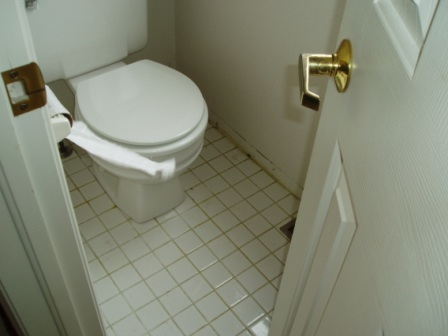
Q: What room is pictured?
A: It is a bathroom.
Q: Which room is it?
A: It is a bathroom.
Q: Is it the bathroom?
A: Yes, it is the bathroom.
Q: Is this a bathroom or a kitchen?
A: It is a bathroom.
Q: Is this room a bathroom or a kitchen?
A: It is a bathroom.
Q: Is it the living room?
A: No, it is the bathroom.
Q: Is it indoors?
A: Yes, it is indoors.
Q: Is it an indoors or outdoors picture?
A: It is indoors.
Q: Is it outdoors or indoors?
A: It is indoors.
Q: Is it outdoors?
A: No, it is indoors.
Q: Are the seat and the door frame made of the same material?
A: Yes, both the seat and the door frame are made of wood.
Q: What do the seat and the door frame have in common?
A: The material, both the seat and the door frame are wooden.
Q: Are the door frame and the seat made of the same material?
A: Yes, both the door frame and the seat are made of wood.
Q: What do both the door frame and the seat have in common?
A: The material, both the door frame and the seat are wooden.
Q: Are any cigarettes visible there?
A: No, there are no cigarettes.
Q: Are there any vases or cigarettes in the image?
A: No, there are no cigarettes or vases.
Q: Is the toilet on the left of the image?
A: Yes, the toilet is on the left of the image.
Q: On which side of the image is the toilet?
A: The toilet is on the left of the image.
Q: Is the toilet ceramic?
A: Yes, the toilet is ceramic.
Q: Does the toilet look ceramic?
A: Yes, the toilet is ceramic.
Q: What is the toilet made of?
A: The toilet is made of porcelain.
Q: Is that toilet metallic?
A: No, the toilet is ceramic.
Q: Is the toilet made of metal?
A: No, the toilet is made of porcelain.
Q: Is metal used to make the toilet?
A: No, the toilet is made of porcelain.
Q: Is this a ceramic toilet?
A: Yes, this is a ceramic toilet.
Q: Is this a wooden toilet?
A: No, this is a ceramic toilet.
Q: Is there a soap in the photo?
A: No, there are no soaps.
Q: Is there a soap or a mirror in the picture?
A: No, there are no soaps or mirrors.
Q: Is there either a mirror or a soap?
A: No, there are no soaps or mirrors.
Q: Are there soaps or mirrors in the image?
A: No, there are no soaps or mirrors.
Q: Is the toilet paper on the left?
A: Yes, the toilet paper is on the left of the image.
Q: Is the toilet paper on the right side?
A: No, the toilet paper is on the left of the image.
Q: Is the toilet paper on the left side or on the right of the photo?
A: The toilet paper is on the left of the image.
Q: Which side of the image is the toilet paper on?
A: The toilet paper is on the left of the image.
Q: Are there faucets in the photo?
A: No, there are no faucets.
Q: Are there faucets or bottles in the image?
A: No, there are no faucets or bottles.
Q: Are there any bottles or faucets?
A: No, there are no faucets or bottles.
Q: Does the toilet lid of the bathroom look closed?
A: Yes, the toilet lid is closed.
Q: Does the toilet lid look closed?
A: Yes, the toilet lid is closed.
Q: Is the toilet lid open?
A: No, the toilet lid is closed.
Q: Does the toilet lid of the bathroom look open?
A: No, the toilet lid is closed.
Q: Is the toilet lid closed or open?
A: The toilet lid is closed.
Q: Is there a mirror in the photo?
A: No, there are no mirrors.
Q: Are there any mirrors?
A: No, there are no mirrors.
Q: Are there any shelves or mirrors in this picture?
A: No, there are no mirrors or shelves.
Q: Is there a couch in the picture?
A: No, there are no couches.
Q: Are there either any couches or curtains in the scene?
A: No, there are no couches or curtains.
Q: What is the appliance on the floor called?
A: The appliance is a heater.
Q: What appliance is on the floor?
A: The appliance is a heater.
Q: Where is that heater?
A: The heater is on the floor.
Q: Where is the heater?
A: The heater is on the floor.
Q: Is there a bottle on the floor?
A: No, there is a heater on the floor.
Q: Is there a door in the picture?
A: Yes, there is a door.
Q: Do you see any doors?
A: Yes, there is a door.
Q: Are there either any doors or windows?
A: Yes, there is a door.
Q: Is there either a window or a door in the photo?
A: Yes, there is a door.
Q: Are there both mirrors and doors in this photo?
A: No, there is a door but no mirrors.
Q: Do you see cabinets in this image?
A: No, there are no cabinets.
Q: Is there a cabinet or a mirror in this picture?
A: No, there are no cabinets or mirrors.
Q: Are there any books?
A: No, there are no books.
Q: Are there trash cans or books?
A: No, there are no books or trash cans.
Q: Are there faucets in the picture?
A: No, there are no faucets.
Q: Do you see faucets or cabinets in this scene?
A: No, there are no faucets or cabinets.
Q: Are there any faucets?
A: No, there are no faucets.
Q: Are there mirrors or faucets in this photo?
A: No, there are no faucets or mirrors.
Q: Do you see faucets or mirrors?
A: No, there are no faucets or mirrors.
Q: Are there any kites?
A: No, there are no kites.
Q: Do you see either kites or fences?
A: No, there are no kites or fences.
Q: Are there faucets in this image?
A: No, there are no faucets.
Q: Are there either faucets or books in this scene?
A: No, there are no faucets or books.